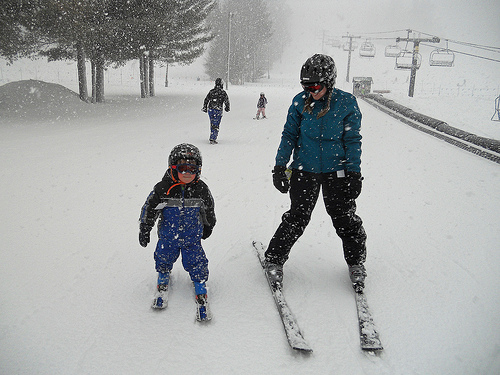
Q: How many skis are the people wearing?
A: Two.